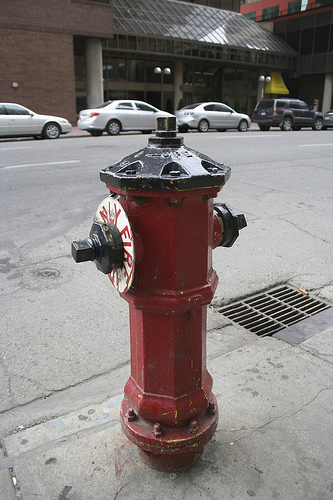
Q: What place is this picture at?
A: It is at the street.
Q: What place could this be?
A: It is a street.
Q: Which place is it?
A: It is a street.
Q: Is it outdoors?
A: Yes, it is outdoors.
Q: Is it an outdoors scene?
A: Yes, it is outdoors.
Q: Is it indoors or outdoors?
A: It is outdoors.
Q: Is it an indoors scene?
A: No, it is outdoors.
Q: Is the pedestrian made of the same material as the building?
A: No, the pedestrian is made of cement and the building is made of glass.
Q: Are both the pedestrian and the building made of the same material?
A: No, the pedestrian is made of cement and the building is made of glass.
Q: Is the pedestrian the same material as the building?
A: No, the pedestrian is made of cement and the building is made of glass.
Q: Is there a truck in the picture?
A: No, there are no trucks.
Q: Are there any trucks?
A: No, there are no trucks.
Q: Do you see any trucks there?
A: No, there are no trucks.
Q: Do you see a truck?
A: No, there are no trucks.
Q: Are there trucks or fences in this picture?
A: No, there are no trucks or fences.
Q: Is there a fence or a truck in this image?
A: No, there are no trucks or fences.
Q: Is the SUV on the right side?
A: Yes, the SUV is on the right of the image.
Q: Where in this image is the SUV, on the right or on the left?
A: The SUV is on the right of the image.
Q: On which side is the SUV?
A: The SUV is on the right of the image.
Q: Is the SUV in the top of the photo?
A: Yes, the SUV is in the top of the image.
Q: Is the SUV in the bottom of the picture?
A: No, the SUV is in the top of the image.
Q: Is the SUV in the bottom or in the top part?
A: The SUV is in the top of the image.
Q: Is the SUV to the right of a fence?
A: No, the SUV is to the right of the car.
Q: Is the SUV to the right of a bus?
A: No, the SUV is to the right of the car.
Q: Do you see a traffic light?
A: No, there are no traffic lights.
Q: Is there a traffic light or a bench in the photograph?
A: No, there are no traffic lights or benches.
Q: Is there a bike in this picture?
A: No, there are no bikes.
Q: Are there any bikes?
A: No, there are no bikes.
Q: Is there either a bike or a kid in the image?
A: No, there are no bikes or children.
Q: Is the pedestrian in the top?
A: Yes, the pedestrian is in the top of the image.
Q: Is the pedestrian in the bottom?
A: No, the pedestrian is in the top of the image.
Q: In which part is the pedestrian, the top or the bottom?
A: The pedestrian is in the top of the image.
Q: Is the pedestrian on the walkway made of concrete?
A: Yes, the pedestrian is made of concrete.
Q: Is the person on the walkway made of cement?
A: Yes, the pedestrian is made of cement.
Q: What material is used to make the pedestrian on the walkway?
A: The pedestrian is made of cement.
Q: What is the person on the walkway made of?
A: The pedestrian is made of cement.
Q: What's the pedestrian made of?
A: The pedestrian is made of concrete.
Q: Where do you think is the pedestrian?
A: The pedestrian is on the walkway.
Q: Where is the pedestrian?
A: The pedestrian is on the walkway.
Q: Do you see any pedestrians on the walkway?
A: Yes, there is a pedestrian on the walkway.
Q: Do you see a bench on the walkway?
A: No, there is a pedestrian on the walkway.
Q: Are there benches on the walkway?
A: No, there is a pedestrian on the walkway.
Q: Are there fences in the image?
A: No, there are no fences.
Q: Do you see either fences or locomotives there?
A: No, there are no fences or locomotives.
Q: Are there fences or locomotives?
A: No, there are no fences or locomotives.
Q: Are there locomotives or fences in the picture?
A: No, there are no fences or locomotives.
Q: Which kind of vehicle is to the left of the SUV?
A: The vehicle is a car.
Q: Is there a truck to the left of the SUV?
A: No, there is a car to the left of the SUV.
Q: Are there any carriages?
A: No, there are no carriages.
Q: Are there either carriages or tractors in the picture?
A: No, there are no carriages or tractors.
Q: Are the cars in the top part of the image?
A: Yes, the cars are in the top of the image.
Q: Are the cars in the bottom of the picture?
A: No, the cars are in the top of the image.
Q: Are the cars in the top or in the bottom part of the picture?
A: The cars are in the top of the image.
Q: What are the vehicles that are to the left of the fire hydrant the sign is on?
A: The vehicles are cars.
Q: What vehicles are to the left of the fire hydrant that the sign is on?
A: The vehicles are cars.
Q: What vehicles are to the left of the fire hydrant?
A: The vehicles are cars.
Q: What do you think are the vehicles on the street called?
A: The vehicles are cars.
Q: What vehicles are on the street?
A: The vehicles are cars.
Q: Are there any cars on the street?
A: Yes, there are cars on the street.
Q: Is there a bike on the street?
A: No, there are cars on the street.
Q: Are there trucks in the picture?
A: No, there are no trucks.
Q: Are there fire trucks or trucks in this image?
A: No, there are no trucks or fire trucks.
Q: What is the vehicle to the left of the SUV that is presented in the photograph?
A: The vehicle is a car.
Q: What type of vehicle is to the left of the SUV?
A: The vehicle is a car.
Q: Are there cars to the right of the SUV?
A: No, the car is to the left of the SUV.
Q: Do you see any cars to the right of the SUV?
A: No, the car is to the left of the SUV.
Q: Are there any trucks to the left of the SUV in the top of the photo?
A: No, there is a car to the left of the SUV.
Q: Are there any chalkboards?
A: No, there are no chalkboards.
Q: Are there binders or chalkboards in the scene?
A: No, there are no chalkboards or binders.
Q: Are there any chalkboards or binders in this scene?
A: No, there are no chalkboards or binders.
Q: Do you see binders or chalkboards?
A: No, there are no chalkboards or binders.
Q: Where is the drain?
A: The drain is in the street.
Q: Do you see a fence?
A: No, there are no fences.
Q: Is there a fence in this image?
A: No, there are no fences.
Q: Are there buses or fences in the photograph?
A: No, there are no fences or buses.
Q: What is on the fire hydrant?
A: The sign is on the fire hydrant.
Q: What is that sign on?
A: The sign is on the fire hydrant.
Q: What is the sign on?
A: The sign is on the fire hydrant.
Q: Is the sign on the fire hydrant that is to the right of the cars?
A: Yes, the sign is on the hydrant.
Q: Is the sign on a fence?
A: No, the sign is on the hydrant.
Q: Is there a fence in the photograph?
A: No, there are no fences.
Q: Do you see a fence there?
A: No, there are no fences.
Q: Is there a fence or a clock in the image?
A: No, there are no fences or clocks.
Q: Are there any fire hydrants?
A: Yes, there is a fire hydrant.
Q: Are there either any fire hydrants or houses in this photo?
A: Yes, there is a fire hydrant.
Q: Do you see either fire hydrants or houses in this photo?
A: Yes, there is a fire hydrant.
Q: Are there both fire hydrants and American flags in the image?
A: No, there is a fire hydrant but no American flags.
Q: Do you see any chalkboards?
A: No, there are no chalkboards.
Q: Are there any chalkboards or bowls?
A: No, there are no chalkboards or bowls.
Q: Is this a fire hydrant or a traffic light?
A: This is a fire hydrant.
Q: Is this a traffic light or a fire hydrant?
A: This is a fire hydrant.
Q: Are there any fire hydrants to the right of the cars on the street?
A: Yes, there is a fire hydrant to the right of the cars.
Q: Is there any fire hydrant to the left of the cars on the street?
A: No, the fire hydrant is to the right of the cars.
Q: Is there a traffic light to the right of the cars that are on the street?
A: No, there is a fire hydrant to the right of the cars.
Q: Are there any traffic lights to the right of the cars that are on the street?
A: No, there is a fire hydrant to the right of the cars.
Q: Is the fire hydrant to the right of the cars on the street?
A: Yes, the fire hydrant is to the right of the cars.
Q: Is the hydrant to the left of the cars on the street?
A: No, the hydrant is to the right of the cars.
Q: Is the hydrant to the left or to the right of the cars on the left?
A: The hydrant is to the right of the cars.